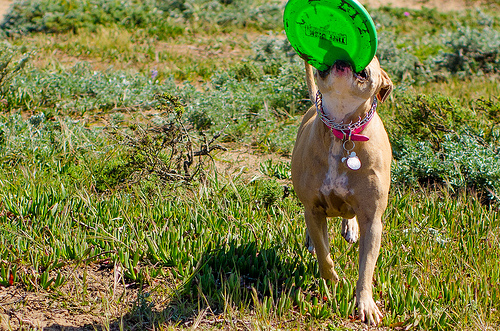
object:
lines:
[207, 136, 298, 188]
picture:
[0, 0, 500, 331]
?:
[340, 182, 347, 187]